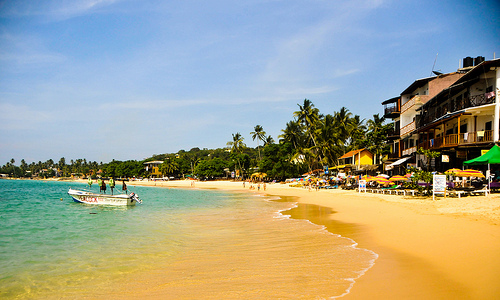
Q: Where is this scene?
A: A beach.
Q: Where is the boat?
A: In the water.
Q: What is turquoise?
A: The ocean.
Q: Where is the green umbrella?
A: In front of the buildings?.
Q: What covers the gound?
A: Sand.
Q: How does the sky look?
A: Clear.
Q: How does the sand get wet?
A: Water rolls up on it.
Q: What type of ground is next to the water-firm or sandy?
A: Sandy.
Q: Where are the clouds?
A: In the sky.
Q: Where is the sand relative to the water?
A: Next to the water.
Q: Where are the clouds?
A: In the sky.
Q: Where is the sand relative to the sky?
A: Beneath the sky.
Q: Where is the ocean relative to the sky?
A: Beneath the sky.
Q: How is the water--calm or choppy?
A: Calm.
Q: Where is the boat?
A: In the water.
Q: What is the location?
A: A beach.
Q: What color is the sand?
A: Brown.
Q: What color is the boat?
A: White.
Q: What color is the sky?
A: Blue.